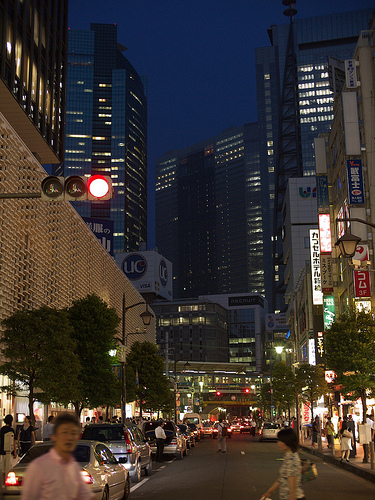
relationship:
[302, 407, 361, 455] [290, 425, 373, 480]
people on sidewalk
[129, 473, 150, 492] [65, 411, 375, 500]
line on road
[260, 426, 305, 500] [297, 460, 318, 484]
woman carrying shoulder bag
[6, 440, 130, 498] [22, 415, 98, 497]
car parked behind man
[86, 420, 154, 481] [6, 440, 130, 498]
car parked in front of car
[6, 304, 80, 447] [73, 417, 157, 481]
tree next to suv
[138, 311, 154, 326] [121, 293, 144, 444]
lamp hanging from pole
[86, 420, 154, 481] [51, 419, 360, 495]
car on street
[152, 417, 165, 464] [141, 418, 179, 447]
man standing by trunk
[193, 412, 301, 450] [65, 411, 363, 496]
people walking in road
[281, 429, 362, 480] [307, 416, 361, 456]
sidewalk crowded with people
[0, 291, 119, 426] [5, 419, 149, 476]
trees on sidewalk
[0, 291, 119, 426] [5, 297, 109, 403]
trees with leaves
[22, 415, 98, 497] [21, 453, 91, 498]
man with shirt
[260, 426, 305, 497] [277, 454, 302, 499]
woman with shirt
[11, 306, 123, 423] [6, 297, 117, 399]
trees with leaves